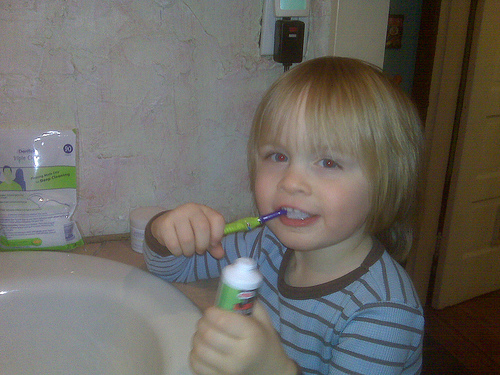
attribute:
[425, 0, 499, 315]
door — white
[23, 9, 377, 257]
wall — multicolored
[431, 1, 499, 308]
door — white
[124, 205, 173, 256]
vat — small, plastic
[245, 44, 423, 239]
hair — blond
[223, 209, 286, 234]
toothbrush — green, purple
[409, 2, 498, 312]
door — open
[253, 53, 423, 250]
kid's hair — blonde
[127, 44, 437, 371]
boy — small, brushing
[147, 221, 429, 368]
shirt — brown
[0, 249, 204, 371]
sink — white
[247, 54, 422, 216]
hair — brown, long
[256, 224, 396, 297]
collar — brown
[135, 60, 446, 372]
child — blue, striped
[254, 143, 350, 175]
eyes — shiny, little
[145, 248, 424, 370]
shirt — striped